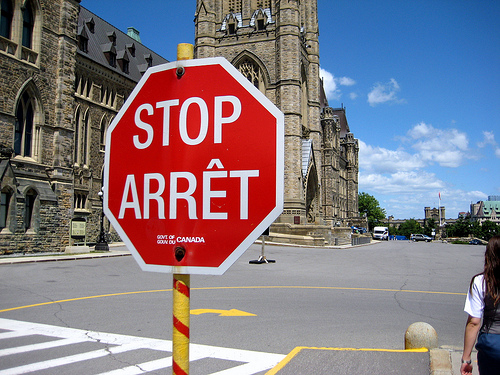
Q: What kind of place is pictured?
A: It is a church.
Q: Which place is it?
A: It is a church.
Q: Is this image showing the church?
A: Yes, it is showing the church.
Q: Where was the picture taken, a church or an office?
A: It was taken at a church.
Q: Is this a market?
A: No, it is a church.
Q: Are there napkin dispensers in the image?
A: No, there are no napkin dispensers.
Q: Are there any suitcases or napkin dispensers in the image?
A: No, there are no napkin dispensers or suitcases.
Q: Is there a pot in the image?
A: No, there are no pots.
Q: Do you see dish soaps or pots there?
A: No, there are no pots or dish soaps.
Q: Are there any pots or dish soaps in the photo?
A: No, there are no pots or dish soaps.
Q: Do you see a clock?
A: No, there are no clocks.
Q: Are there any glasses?
A: No, there are no glasses.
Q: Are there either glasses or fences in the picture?
A: No, there are no glasses or fences.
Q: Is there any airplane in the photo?
A: No, there are no airplanes.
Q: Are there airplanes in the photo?
A: No, there are no airplanes.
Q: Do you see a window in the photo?
A: Yes, there is a window.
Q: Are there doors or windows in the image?
A: Yes, there is a window.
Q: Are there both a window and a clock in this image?
A: No, there is a window but no clocks.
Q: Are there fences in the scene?
A: No, there are no fences.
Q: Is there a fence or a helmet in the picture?
A: No, there are no fences or helmets.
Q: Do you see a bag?
A: No, there are no bags.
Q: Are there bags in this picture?
A: No, there are no bags.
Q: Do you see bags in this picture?
A: No, there are no bags.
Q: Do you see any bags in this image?
A: No, there are no bags.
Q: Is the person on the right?
A: Yes, the person is on the right of the image.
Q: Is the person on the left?
A: No, the person is on the right of the image.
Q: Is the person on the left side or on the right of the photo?
A: The person is on the right of the image.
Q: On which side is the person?
A: The person is on the right of the image.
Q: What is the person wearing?
A: The person is wearing a shirt.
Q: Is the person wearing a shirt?
A: Yes, the person is wearing a shirt.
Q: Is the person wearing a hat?
A: No, the person is wearing a shirt.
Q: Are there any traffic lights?
A: No, there are no traffic lights.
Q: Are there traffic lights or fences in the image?
A: No, there are no traffic lights or fences.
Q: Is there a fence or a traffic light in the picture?
A: No, there are no traffic lights or fences.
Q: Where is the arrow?
A: The arrow is on the pavement.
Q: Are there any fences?
A: No, there are no fences.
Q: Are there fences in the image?
A: No, there are no fences.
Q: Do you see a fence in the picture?
A: No, there are no fences.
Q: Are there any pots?
A: No, there are no pots.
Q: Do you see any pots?
A: No, there are no pots.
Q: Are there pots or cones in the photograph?
A: No, there are no pots or cones.